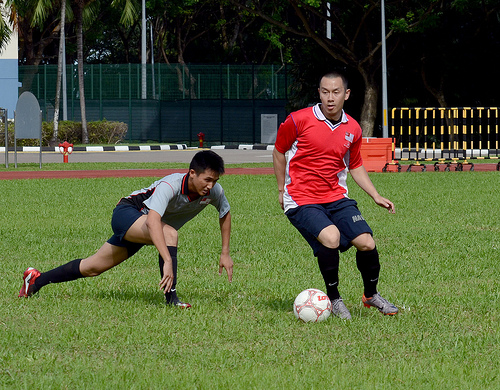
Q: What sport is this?
A: Soccer.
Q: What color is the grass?
A: Green.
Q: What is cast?
A: Shadow.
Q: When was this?
A: Daytime.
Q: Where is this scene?
A: Soccer field.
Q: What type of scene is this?
A: Outdoor.